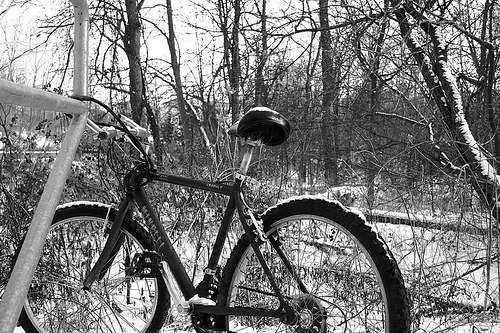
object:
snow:
[306, 248, 310, 252]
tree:
[143, 0, 196, 163]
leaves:
[181, 6, 183, 9]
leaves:
[189, 52, 192, 54]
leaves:
[36, 34, 41, 38]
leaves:
[195, 14, 199, 18]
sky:
[2, 0, 68, 73]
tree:
[316, 0, 340, 184]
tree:
[386, 0, 500, 213]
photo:
[0, 0, 495, 331]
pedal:
[127, 252, 162, 278]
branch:
[378, 111, 427, 128]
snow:
[443, 61, 450, 74]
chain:
[239, 287, 276, 296]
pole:
[351, 207, 495, 236]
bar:
[73, 16, 88, 98]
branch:
[268, 26, 314, 39]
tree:
[217, 2, 242, 125]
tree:
[106, 0, 156, 162]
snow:
[281, 198, 288, 203]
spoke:
[298, 219, 301, 244]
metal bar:
[0, 79, 90, 114]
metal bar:
[1, 113, 87, 332]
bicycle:
[9, 104, 412, 333]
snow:
[250, 106, 270, 111]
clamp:
[234, 173, 259, 187]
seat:
[226, 107, 289, 146]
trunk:
[454, 115, 500, 213]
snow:
[300, 195, 314, 199]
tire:
[215, 195, 410, 333]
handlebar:
[97, 130, 118, 140]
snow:
[71, 200, 92, 204]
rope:
[76, 95, 125, 126]